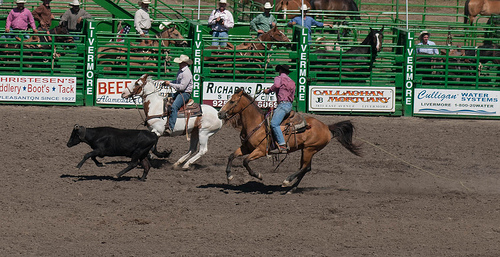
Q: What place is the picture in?
A: It is at the field.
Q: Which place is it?
A: It is a field.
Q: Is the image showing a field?
A: Yes, it is showing a field.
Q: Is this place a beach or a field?
A: It is a field.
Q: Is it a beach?
A: No, it is a field.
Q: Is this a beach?
A: No, it is a field.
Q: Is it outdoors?
A: Yes, it is outdoors.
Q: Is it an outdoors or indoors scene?
A: It is outdoors.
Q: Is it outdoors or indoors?
A: It is outdoors.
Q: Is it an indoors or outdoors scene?
A: It is outdoors.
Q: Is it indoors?
A: No, it is outdoors.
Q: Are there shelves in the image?
A: No, there are no shelves.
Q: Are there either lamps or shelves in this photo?
A: No, there are no shelves or lamps.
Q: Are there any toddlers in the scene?
A: No, there are no toddlers.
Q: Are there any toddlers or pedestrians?
A: No, there are no toddlers or pedestrians.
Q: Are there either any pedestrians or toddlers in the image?
A: No, there are no toddlers or pedestrians.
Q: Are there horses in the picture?
A: Yes, there is a horse.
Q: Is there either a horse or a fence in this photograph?
A: Yes, there is a horse.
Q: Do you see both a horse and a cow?
A: Yes, there are both a horse and a cow.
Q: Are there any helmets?
A: No, there are no helmets.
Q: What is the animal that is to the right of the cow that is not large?
A: The animal is a horse.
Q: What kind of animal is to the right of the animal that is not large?
A: The animal is a horse.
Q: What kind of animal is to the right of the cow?
A: The animal is a horse.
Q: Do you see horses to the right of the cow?
A: Yes, there is a horse to the right of the cow.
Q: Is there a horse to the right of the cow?
A: Yes, there is a horse to the right of the cow.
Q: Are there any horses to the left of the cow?
A: No, the horse is to the right of the cow.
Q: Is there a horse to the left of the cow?
A: No, the horse is to the right of the cow.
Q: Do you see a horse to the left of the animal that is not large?
A: No, the horse is to the right of the cow.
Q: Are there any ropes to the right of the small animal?
A: No, there is a horse to the right of the cow.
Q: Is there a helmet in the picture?
A: No, there are no helmets.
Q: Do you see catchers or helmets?
A: No, there are no helmets or catchers.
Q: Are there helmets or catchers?
A: No, there are no helmets or catchers.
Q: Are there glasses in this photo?
A: No, there are no glasses.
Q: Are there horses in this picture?
A: Yes, there is a horse.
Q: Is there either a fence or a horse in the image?
A: Yes, there is a horse.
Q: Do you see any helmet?
A: No, there are no helmets.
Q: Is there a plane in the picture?
A: No, there are no airplanes.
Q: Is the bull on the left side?
A: Yes, the bull is on the left of the image.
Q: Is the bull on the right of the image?
A: No, the bull is on the left of the image.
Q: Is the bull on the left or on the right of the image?
A: The bull is on the left of the image.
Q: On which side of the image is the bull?
A: The bull is on the left of the image.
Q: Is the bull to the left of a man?
A: Yes, the bull is to the left of a man.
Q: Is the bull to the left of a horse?
A: Yes, the bull is to the left of a horse.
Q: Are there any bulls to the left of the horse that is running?
A: Yes, there is a bull to the left of the horse.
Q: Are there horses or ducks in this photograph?
A: Yes, there is a horse.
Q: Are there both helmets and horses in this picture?
A: No, there is a horse but no helmets.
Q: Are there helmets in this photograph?
A: No, there are no helmets.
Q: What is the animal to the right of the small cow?
A: The animal is a horse.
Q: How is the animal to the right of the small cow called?
A: The animal is a horse.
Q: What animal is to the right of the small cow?
A: The animal is a horse.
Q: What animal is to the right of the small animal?
A: The animal is a horse.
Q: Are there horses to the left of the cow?
A: No, the horse is to the right of the cow.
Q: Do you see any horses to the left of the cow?
A: No, the horse is to the right of the cow.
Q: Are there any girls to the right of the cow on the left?
A: No, there is a horse to the right of the cow.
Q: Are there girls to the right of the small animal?
A: No, there is a horse to the right of the cow.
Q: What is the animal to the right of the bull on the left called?
A: The animal is a horse.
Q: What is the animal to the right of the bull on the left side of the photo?
A: The animal is a horse.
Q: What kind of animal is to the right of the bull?
A: The animal is a horse.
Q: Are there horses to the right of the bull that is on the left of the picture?
A: Yes, there is a horse to the right of the bull.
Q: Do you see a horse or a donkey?
A: Yes, there is a horse.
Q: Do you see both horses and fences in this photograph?
A: Yes, there are both a horse and a fence.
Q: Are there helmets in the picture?
A: No, there are no helmets.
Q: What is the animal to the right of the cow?
A: The animal is a horse.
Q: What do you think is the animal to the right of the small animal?
A: The animal is a horse.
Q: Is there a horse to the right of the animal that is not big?
A: Yes, there is a horse to the right of the cow.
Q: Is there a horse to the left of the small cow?
A: No, the horse is to the right of the cow.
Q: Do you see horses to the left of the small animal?
A: No, the horse is to the right of the cow.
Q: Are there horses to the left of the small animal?
A: No, the horse is to the right of the cow.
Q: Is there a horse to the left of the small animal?
A: No, the horse is to the right of the cow.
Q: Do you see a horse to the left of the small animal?
A: No, the horse is to the right of the cow.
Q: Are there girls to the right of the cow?
A: No, there is a horse to the right of the cow.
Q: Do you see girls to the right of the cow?
A: No, there is a horse to the right of the cow.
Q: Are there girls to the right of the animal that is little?
A: No, there is a horse to the right of the cow.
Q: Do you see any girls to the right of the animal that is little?
A: No, there is a horse to the right of the cow.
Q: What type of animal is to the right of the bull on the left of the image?
A: The animal is a horse.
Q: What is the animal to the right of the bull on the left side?
A: The animal is a horse.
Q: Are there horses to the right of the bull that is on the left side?
A: Yes, there is a horse to the right of the bull.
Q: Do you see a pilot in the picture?
A: No, there are no pilots.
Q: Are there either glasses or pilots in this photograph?
A: No, there are no pilots or glasses.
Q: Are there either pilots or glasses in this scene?
A: No, there are no pilots or glasses.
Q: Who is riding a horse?
A: The man is riding a horse.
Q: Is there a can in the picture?
A: No, there are no cans.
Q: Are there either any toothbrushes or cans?
A: No, there are no cans or toothbrushes.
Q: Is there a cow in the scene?
A: Yes, there is a cow.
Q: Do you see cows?
A: Yes, there is a cow.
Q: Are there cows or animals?
A: Yes, there is a cow.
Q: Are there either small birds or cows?
A: Yes, there is a small cow.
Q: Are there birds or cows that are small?
A: Yes, the cow is small.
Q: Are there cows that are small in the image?
A: Yes, there is a small cow.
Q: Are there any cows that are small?
A: Yes, there is a cow that is small.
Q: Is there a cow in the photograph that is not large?
A: Yes, there is a small cow.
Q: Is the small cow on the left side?
A: Yes, the cow is on the left of the image.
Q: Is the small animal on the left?
A: Yes, the cow is on the left of the image.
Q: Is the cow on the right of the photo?
A: No, the cow is on the left of the image.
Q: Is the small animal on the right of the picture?
A: No, the cow is on the left of the image.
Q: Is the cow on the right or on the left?
A: The cow is on the left of the image.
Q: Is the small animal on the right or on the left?
A: The cow is on the left of the image.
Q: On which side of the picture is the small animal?
A: The cow is on the left of the image.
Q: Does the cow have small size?
A: Yes, the cow is small.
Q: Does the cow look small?
A: Yes, the cow is small.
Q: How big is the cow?
A: The cow is small.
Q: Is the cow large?
A: No, the cow is small.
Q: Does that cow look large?
A: No, the cow is small.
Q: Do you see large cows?
A: No, there is a cow but it is small.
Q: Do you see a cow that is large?
A: No, there is a cow but it is small.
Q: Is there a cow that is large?
A: No, there is a cow but it is small.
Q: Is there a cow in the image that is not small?
A: No, there is a cow but it is small.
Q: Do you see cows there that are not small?
A: No, there is a cow but it is small.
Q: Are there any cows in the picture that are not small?
A: No, there is a cow but it is small.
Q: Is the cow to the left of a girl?
A: No, the cow is to the left of a horse.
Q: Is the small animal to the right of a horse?
A: No, the cow is to the left of a horse.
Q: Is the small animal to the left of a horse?
A: Yes, the cow is to the left of a horse.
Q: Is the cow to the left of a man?
A: Yes, the cow is to the left of a man.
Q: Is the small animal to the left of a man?
A: Yes, the cow is to the left of a man.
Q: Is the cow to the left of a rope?
A: No, the cow is to the left of a man.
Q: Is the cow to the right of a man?
A: No, the cow is to the left of a man.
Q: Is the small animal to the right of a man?
A: No, the cow is to the left of a man.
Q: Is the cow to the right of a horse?
A: No, the cow is to the left of a horse.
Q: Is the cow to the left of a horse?
A: Yes, the cow is to the left of a horse.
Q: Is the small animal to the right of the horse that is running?
A: No, the cow is to the left of the horse.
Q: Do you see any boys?
A: No, there are no boys.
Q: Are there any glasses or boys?
A: No, there are no boys or glasses.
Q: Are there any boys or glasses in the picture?
A: No, there are no boys or glasses.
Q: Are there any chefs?
A: No, there are no chefs.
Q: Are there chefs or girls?
A: No, there are no chefs or girls.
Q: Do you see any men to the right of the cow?
A: Yes, there is a man to the right of the cow.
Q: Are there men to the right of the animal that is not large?
A: Yes, there is a man to the right of the cow.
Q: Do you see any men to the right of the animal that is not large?
A: Yes, there is a man to the right of the cow.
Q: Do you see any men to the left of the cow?
A: No, the man is to the right of the cow.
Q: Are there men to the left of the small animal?
A: No, the man is to the right of the cow.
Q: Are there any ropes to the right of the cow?
A: No, there is a man to the right of the cow.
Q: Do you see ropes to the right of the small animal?
A: No, there is a man to the right of the cow.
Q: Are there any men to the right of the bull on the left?
A: Yes, there is a man to the right of the bull.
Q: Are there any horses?
A: Yes, there is a horse.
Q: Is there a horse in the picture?
A: Yes, there is a horse.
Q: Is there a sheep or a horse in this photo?
A: Yes, there is a horse.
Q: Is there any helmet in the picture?
A: No, there are no helmets.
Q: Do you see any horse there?
A: Yes, there is a horse.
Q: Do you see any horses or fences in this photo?
A: Yes, there is a horse.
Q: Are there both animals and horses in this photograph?
A: Yes, there are both a horse and an animal.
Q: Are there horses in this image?
A: Yes, there is a horse.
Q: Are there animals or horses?
A: Yes, there is a horse.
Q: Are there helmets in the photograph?
A: No, there are no helmets.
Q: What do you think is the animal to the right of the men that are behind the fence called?
A: The animal is a horse.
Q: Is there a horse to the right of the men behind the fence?
A: Yes, there is a horse to the right of the men.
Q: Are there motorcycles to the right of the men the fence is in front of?
A: No, there is a horse to the right of the men.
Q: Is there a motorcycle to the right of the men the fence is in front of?
A: No, there is a horse to the right of the men.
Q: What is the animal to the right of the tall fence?
A: The animal is a horse.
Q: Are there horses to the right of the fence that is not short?
A: Yes, there is a horse to the right of the fence.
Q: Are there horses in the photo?
A: Yes, there is a horse.